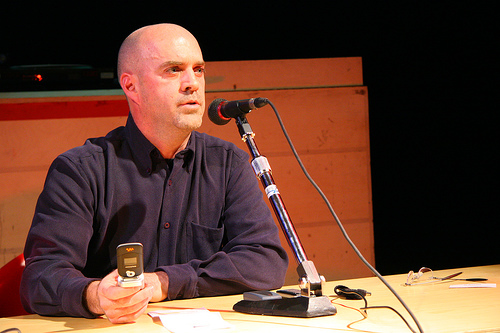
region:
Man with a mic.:
[63, 1, 368, 296]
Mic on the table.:
[210, 102, 357, 325]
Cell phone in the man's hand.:
[60, 217, 237, 307]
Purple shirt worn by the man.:
[11, 127, 223, 301]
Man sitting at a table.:
[32, 27, 467, 329]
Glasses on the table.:
[368, 224, 472, 281]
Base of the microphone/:
[216, 257, 305, 329]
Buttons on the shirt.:
[140, 141, 213, 289]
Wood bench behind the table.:
[260, 57, 409, 189]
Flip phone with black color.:
[107, 228, 160, 305]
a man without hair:
[105, 20, 216, 145]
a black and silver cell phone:
[115, 236, 140, 301]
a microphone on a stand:
[204, 89, 314, 319]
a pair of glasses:
[396, 247, 448, 305]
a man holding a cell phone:
[11, 29, 245, 321]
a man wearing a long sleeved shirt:
[12, 20, 214, 305]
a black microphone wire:
[261, 85, 426, 329]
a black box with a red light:
[17, 61, 52, 103]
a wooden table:
[227, 265, 490, 330]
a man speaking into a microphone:
[85, 14, 235, 201]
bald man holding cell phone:
[22, 15, 291, 317]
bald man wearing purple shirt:
[13, 19, 299, 325]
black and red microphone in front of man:
[206, 85, 336, 327]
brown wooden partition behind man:
[6, 44, 396, 316]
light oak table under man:
[3, 252, 498, 329]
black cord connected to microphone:
[253, 94, 443, 331]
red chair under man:
[1, 245, 62, 314]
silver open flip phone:
[112, 233, 154, 315]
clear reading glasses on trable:
[403, 260, 468, 290]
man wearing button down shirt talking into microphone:
[18, 16, 300, 325]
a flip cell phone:
[111, 237, 161, 291]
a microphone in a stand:
[196, 90, 304, 131]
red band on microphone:
[203, 91, 236, 121]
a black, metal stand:
[220, 91, 335, 326]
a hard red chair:
[1, 237, 65, 324]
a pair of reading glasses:
[393, 252, 498, 290]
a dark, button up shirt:
[18, 109, 318, 311]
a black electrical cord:
[330, 260, 439, 330]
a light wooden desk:
[6, 252, 498, 332]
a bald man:
[27, 12, 309, 292]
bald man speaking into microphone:
[106, 17, 291, 167]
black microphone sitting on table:
[208, 89, 338, 328]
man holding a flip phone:
[95, 233, 157, 329]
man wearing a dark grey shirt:
[28, 20, 212, 235]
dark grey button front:
[146, 152, 182, 262]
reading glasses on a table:
[396, 260, 496, 300]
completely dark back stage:
[376, 22, 486, 232]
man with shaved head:
[108, 16, 211, 164]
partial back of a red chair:
[0, 242, 35, 320]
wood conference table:
[373, 286, 494, 328]